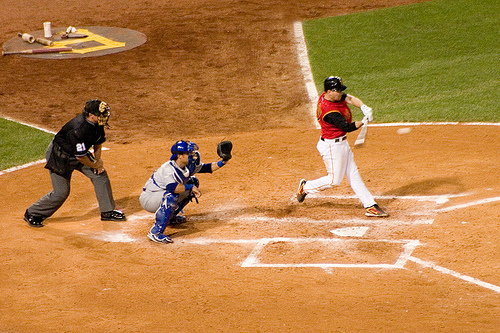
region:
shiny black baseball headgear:
[323, 70, 348, 98]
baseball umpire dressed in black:
[25, 91, 127, 260]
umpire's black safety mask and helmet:
[74, 93, 122, 145]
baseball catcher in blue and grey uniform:
[124, 120, 255, 260]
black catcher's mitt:
[208, 132, 246, 169]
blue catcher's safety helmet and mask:
[164, 133, 207, 173]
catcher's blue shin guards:
[145, 188, 194, 255]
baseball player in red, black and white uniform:
[286, 70, 397, 235]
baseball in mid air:
[384, 110, 436, 163]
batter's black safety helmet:
[314, 62, 359, 112]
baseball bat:
[355, 109, 373, 162]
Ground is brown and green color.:
[28, 31, 448, 282]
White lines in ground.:
[117, 133, 467, 318]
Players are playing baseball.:
[29, 83, 431, 249]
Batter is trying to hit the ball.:
[275, 58, 413, 223]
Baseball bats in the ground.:
[15, 20, 97, 63]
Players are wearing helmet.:
[48, 70, 381, 220]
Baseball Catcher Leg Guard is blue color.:
[150, 190, 177, 241]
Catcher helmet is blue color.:
[151, 131, 216, 246]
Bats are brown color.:
[5, 15, 78, 66]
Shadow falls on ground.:
[20, 174, 467, 264]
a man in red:
[262, 48, 470, 265]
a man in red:
[310, 34, 378, 236]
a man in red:
[301, 1, 394, 322]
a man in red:
[274, 80, 386, 247]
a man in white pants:
[311, 42, 465, 270]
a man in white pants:
[304, 55, 386, 196]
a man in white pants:
[337, 52, 414, 324]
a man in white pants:
[292, 1, 386, 289]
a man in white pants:
[318, 98, 390, 289]